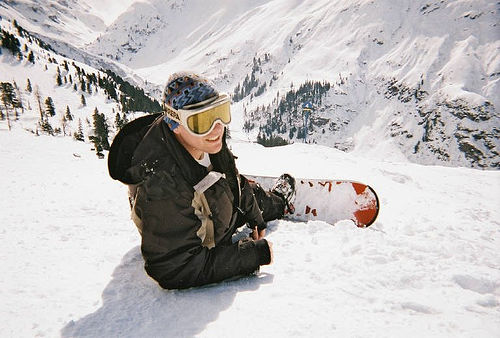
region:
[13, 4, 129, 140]
snow covered mountains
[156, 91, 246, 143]
ski goggles on man's face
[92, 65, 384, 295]
man sitting on snow with snowboard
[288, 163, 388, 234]
red and white snowboard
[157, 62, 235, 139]
knit hat on snowboarders head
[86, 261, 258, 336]
shadow cast on ground by man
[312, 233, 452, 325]
ground covered with white snow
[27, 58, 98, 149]
green trees scattered on mountains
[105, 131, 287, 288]
winter jacket worn by snowboarder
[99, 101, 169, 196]
hood of winter jacket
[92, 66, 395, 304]
snow boarder resting in the show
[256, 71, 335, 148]
pine trees growing on a mountain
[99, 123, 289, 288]
black and tan winter jacket with a hood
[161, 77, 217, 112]
blue and purple winter hat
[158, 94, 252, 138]
white and gold ski goggles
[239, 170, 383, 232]
red and white snow board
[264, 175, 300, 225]
snowboard boot clipped to snowboard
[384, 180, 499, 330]
snow with footprints in it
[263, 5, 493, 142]
mountain slope covered in snow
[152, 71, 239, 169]
smiling Caucasian snow boarder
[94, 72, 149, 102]
trees in the distance.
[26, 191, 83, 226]
snow on the ground.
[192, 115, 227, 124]
goggles on snowboarder's face.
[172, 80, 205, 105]
hat on snowboarder's head.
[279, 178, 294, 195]
boot on snowboarder's foot.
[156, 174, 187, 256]
sleeve of snowboarder's coat.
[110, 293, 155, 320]
shadow of the snowboarder.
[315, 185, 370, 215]
snowboard with snow on it.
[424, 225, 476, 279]
footprints in the snow.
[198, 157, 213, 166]
white t-shirt underneath the coat.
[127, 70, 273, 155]
the man is wearing ski goggles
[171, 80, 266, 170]
the ski goggles are yellow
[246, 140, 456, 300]
the man is on a snowboard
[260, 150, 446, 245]
the snowboard is orange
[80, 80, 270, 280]
the man's jacket is black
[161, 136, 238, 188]
the man's shirt is white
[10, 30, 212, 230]
trees are in the snow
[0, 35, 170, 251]
the trees are pine trees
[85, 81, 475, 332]
the man is laying in the snow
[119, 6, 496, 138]
the mountains are covered in snow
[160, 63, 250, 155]
Man wearing goggles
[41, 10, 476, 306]
Man laying on snow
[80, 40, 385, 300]
Man wearing jacket with snowboard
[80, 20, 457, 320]
Man smiling in the snow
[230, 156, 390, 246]
Foot strapped to snowboard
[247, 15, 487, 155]
Snow covered landscape with some trees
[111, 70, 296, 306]
Man wearing a beanie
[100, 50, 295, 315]
Man wearing a hooded jacket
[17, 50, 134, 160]
Greens trees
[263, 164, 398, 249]
Red snowboard covered with snow